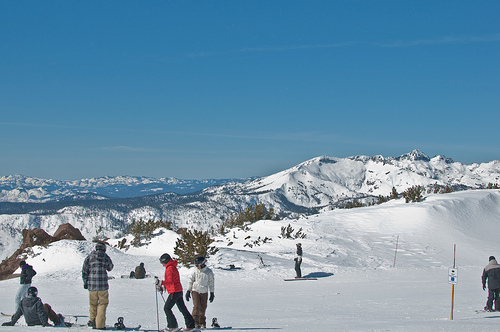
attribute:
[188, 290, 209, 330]
pants — brown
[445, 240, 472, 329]
markers — pole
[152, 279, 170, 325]
poles — ski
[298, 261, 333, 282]
shadow — skier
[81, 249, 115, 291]
jacket — blue, black, plaid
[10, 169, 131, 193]
distance — far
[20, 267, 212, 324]
skiers — some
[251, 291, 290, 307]
snow — white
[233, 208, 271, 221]
shrubs — green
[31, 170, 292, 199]
mountains — row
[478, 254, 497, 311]
skier — gray, white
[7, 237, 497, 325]
people — group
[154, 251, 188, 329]
woman — red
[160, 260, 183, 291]
coat — puffy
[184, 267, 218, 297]
coat — puffy, white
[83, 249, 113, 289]
jacket — plaid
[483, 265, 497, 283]
coat — light, dark, gray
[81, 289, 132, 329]
pants — tan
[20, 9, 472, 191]
sky — blue